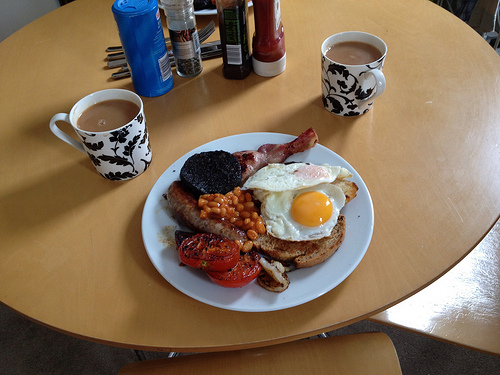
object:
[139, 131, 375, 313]
plate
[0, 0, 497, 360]
table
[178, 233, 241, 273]
tomato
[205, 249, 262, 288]
tomato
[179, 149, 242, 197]
sausage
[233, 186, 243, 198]
beans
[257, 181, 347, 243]
egg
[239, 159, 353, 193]
egg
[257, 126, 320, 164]
bacon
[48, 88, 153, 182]
cup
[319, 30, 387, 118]
cup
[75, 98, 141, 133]
coffee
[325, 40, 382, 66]
coffee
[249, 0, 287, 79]
ketchup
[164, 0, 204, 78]
pepper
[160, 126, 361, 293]
food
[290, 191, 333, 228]
yolk up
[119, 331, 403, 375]
chair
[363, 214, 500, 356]
chair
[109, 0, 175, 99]
salt shaker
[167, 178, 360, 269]
toast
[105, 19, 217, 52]
fork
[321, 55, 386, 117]
pattern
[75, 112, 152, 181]
pattern